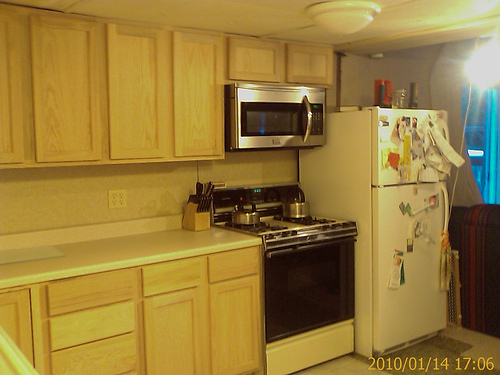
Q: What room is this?
A: Kitchen.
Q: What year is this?
A: 2010.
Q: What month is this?
A: January.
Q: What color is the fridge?
A: White.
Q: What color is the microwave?
A: Silver.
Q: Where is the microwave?
A: Above the stove.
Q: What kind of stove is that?
A: Gas.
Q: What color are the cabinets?
A: Yellow.